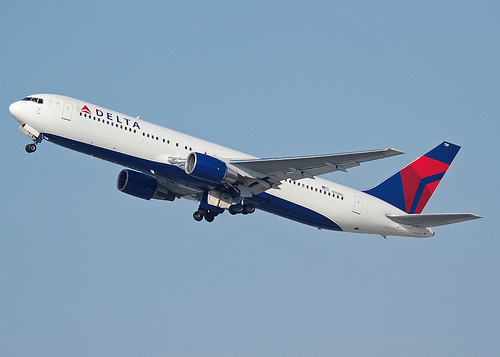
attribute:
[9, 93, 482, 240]
plane — white, flying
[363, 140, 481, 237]
tail — red, blue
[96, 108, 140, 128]
word — blue, painted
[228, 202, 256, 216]
back wheels — lowered, down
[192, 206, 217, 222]
back wheels — lowered, down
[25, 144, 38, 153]
front wheels — down, lowered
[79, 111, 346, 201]
row of windows — numerous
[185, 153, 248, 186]
engine — blue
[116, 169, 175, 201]
engine — blue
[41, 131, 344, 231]
underbelly — blue